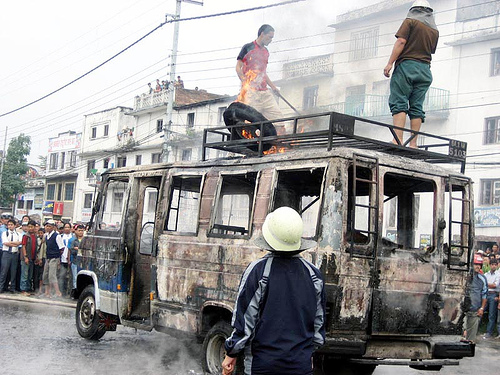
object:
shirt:
[236, 40, 269, 90]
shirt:
[394, 17, 440, 66]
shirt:
[45, 230, 65, 258]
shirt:
[224, 252, 328, 375]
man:
[220, 206, 324, 373]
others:
[233, 23, 286, 153]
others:
[382, 0, 439, 150]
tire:
[75, 284, 108, 341]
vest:
[45, 231, 61, 258]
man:
[42, 219, 65, 298]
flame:
[234, 67, 258, 105]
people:
[146, 76, 185, 92]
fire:
[234, 66, 305, 154]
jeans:
[19, 259, 33, 291]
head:
[262, 206, 304, 256]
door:
[124, 170, 158, 327]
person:
[0, 214, 117, 298]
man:
[235, 23, 284, 130]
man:
[382, 0, 439, 150]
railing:
[225, 110, 433, 162]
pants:
[388, 59, 434, 123]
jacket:
[224, 252, 328, 374]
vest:
[20, 232, 38, 260]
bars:
[353, 35, 378, 61]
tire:
[222, 101, 277, 151]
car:
[69, 110, 475, 374]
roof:
[106, 146, 474, 179]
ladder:
[350, 152, 381, 259]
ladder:
[446, 173, 475, 271]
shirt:
[1, 229, 23, 253]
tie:
[7, 232, 14, 252]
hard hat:
[262, 206, 304, 251]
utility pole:
[160, 0, 181, 163]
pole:
[161, 0, 205, 163]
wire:
[0, 0, 302, 117]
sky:
[0, 0, 381, 168]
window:
[186, 112, 194, 128]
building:
[72, 88, 241, 235]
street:
[0, 287, 499, 374]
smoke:
[0, 5, 495, 349]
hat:
[43, 219, 55, 225]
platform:
[200, 110, 468, 174]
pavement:
[0, 288, 499, 374]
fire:
[235, 68, 260, 105]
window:
[351, 27, 377, 62]